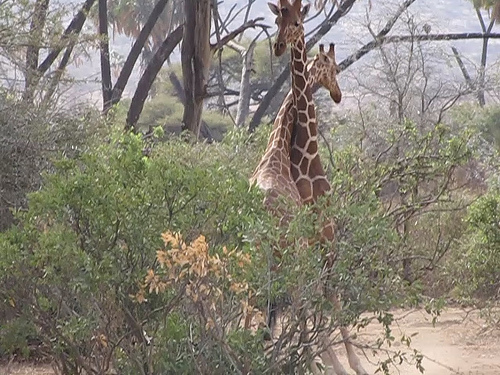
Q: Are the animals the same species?
A: Yes, all the animals are giraffes.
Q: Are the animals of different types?
A: No, all the animals are giraffes.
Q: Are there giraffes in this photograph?
A: Yes, there is a giraffe.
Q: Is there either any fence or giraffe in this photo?
A: Yes, there is a giraffe.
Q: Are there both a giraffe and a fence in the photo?
A: No, there is a giraffe but no fences.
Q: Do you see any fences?
A: No, there are no fences.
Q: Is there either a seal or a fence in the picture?
A: No, there are no fences or seals.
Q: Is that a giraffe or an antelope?
A: That is a giraffe.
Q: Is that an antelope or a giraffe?
A: That is a giraffe.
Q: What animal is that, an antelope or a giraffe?
A: That is a giraffe.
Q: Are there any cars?
A: No, there are no cars.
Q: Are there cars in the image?
A: No, there are no cars.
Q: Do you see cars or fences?
A: No, there are no cars or fences.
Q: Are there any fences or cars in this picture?
A: No, there are no cars or fences.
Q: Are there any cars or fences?
A: No, there are no cars or fences.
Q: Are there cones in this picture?
A: No, there are no cones.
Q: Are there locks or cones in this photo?
A: No, there are no cones or locks.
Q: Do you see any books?
A: No, there are no books.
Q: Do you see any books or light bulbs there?
A: No, there are no books or light bulbs.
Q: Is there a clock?
A: No, there are no clocks.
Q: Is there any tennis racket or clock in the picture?
A: No, there are no clocks or rackets.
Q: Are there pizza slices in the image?
A: No, there are no pizza slices.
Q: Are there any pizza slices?
A: No, there are no pizza slices.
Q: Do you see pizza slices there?
A: No, there are no pizza slices.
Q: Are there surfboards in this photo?
A: No, there are no surfboards.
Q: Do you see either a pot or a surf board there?
A: No, there are no surfboards or pots.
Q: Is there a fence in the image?
A: No, there are no fences.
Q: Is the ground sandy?
A: Yes, the ground is sandy.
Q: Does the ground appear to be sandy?
A: Yes, the ground is sandy.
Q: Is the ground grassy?
A: No, the ground is sandy.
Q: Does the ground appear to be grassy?
A: No, the ground is sandy.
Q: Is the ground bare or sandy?
A: The ground is sandy.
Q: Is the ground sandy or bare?
A: The ground is sandy.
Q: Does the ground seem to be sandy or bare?
A: The ground is sandy.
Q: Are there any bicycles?
A: No, there are no bicycles.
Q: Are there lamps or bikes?
A: No, there are no bikes or lamps.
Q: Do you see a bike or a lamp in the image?
A: No, there are no bikes or lamps.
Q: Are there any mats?
A: No, there are no mats.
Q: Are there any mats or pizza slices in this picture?
A: No, there are no mats or pizza slices.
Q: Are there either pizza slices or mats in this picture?
A: No, there are no mats or pizza slices.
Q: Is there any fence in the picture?
A: No, there are no fences.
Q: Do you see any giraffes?
A: Yes, there is a giraffe.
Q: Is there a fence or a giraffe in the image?
A: Yes, there is a giraffe.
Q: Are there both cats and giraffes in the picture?
A: No, there is a giraffe but no cats.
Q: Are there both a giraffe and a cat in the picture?
A: No, there is a giraffe but no cats.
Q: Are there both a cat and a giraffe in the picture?
A: No, there is a giraffe but no cats.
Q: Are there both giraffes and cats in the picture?
A: No, there is a giraffe but no cats.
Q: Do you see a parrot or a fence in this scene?
A: No, there are no fences or parrots.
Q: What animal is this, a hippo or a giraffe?
A: This is a giraffe.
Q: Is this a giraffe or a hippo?
A: This is a giraffe.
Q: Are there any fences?
A: No, there are no fences.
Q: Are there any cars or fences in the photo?
A: No, there are no fences or cars.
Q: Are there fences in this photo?
A: No, there are no fences.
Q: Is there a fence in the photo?
A: No, there are no fences.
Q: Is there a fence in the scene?
A: No, there are no fences.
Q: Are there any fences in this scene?
A: No, there are no fences.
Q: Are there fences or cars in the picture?
A: No, there are no fences or cars.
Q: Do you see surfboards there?
A: No, there are no surfboards.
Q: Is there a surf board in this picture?
A: No, there are no surfboards.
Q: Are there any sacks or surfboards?
A: No, there are no surfboards or sacks.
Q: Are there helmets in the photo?
A: No, there are no helmets.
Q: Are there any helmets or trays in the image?
A: No, there are no helmets or trays.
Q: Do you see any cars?
A: No, there are no cars.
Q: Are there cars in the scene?
A: No, there are no cars.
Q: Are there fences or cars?
A: No, there are no cars or fences.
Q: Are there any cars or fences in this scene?
A: No, there are no cars or fences.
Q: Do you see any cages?
A: No, there are no cages.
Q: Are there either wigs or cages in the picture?
A: No, there are no cages or wigs.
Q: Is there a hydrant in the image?
A: No, there are no fire hydrants.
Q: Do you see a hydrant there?
A: No, there are no fire hydrants.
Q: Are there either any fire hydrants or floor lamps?
A: No, there are no fire hydrants or floor lamps.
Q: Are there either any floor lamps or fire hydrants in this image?
A: No, there are no fire hydrants or floor lamps.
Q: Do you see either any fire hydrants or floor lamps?
A: No, there are no fire hydrants or floor lamps.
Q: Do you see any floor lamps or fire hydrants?
A: No, there are no fire hydrants or floor lamps.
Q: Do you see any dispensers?
A: No, there are no dispensers.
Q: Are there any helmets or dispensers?
A: No, there are no dispensers or helmets.